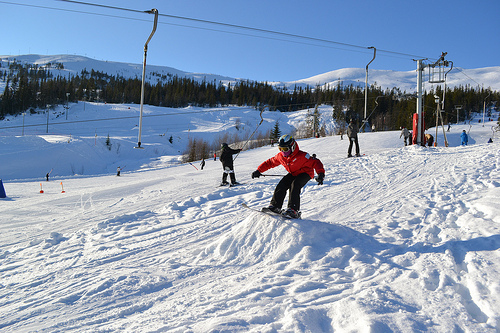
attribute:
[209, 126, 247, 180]
jacket — black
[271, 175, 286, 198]
knee — bent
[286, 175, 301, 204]
knee — bent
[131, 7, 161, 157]
ski lift — empty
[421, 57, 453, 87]
lift — ski, metal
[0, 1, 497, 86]
sky — clear, bright, blue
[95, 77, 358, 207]
slope — small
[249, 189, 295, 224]
skis — snow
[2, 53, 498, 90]
mountain — snow-covered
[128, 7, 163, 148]
poles — hanging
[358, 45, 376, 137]
poles — hanging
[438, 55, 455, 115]
poles — hanging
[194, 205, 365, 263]
ramp — small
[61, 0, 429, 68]
wire — elevated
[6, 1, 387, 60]
wire — elevated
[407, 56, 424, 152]
pole — tall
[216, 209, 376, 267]
mound — small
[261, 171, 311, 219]
pants — black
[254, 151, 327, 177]
jacket — red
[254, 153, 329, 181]
jacket — red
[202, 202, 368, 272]
mound — small